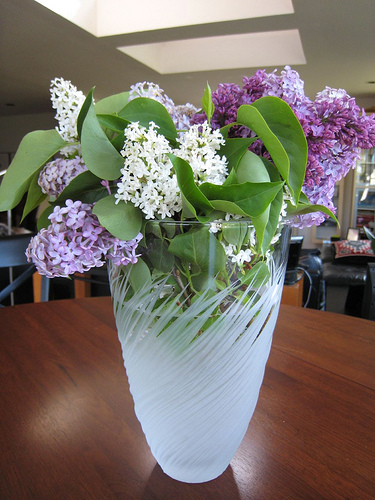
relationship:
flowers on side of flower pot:
[189, 63, 374, 229] [105, 225, 290, 483]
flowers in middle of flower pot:
[116, 120, 229, 222] [1, 67, 365, 483]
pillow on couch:
[332, 239, 373, 258] [315, 230, 374, 290]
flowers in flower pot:
[0, 64, 373, 280] [105, 225, 290, 483]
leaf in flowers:
[0, 129, 65, 211] [0, 64, 373, 280]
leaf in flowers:
[76, 85, 125, 181] [0, 64, 373, 280]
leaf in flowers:
[116, 97, 178, 140] [0, 64, 373, 280]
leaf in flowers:
[91, 195, 143, 240] [0, 64, 373, 280]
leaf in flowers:
[237, 94, 307, 208] [0, 64, 373, 280]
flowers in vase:
[0, 64, 374, 329] [106, 257, 287, 483]